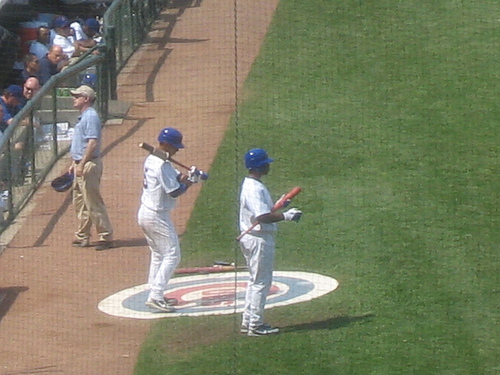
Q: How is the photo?
A: Clear.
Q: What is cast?
A: Shadow.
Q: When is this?
A: Daytime.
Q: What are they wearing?
A: Hats.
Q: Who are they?
A: Players.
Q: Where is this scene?
A: At a baseball field.